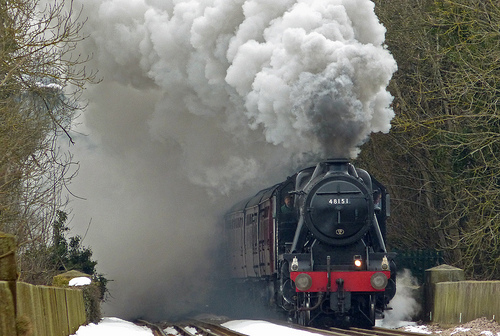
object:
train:
[200, 156, 391, 327]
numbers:
[327, 199, 334, 205]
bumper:
[292, 271, 395, 293]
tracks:
[144, 315, 246, 334]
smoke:
[62, 0, 394, 312]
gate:
[426, 267, 499, 325]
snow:
[83, 319, 142, 336]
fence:
[3, 281, 86, 334]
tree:
[3, 1, 73, 271]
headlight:
[294, 272, 315, 291]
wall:
[85, 282, 99, 325]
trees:
[432, 4, 500, 281]